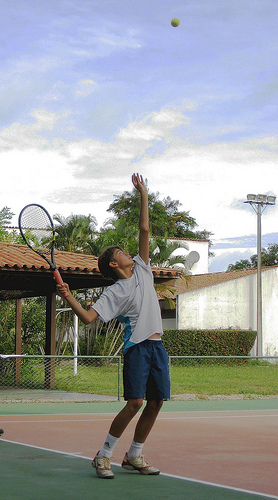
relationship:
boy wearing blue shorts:
[55, 173, 170, 480] [116, 338, 173, 409]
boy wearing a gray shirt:
[55, 173, 170, 480] [90, 254, 164, 352]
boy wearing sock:
[55, 173, 170, 480] [100, 433, 120, 460]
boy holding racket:
[55, 173, 170, 480] [18, 202, 70, 296]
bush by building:
[167, 319, 259, 361] [79, 235, 268, 364]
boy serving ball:
[55, 173, 170, 480] [165, 10, 182, 29]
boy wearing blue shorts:
[20, 163, 193, 473] [110, 326, 197, 430]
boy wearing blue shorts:
[55, 173, 170, 480] [123, 338, 170, 402]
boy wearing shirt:
[55, 173, 170, 480] [90, 272, 187, 337]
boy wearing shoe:
[55, 173, 170, 480] [122, 452, 161, 475]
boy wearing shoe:
[55, 173, 170, 480] [91, 449, 115, 479]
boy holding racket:
[55, 173, 170, 480] [14, 199, 71, 298]